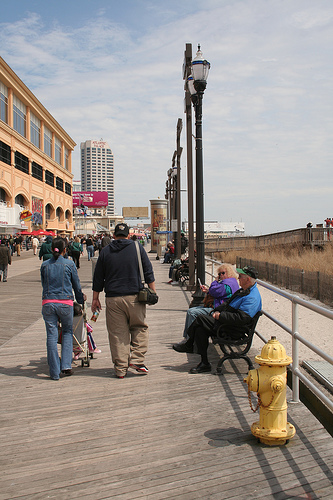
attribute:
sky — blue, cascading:
[1, 0, 332, 236]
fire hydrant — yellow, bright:
[245, 335, 293, 447]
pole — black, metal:
[194, 79, 205, 290]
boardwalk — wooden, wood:
[2, 246, 332, 499]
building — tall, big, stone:
[81, 140, 114, 216]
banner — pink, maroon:
[73, 190, 109, 208]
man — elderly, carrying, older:
[172, 264, 262, 372]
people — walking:
[1, 224, 157, 377]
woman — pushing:
[39, 238, 86, 379]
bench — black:
[212, 310, 263, 375]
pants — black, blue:
[191, 310, 256, 356]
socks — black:
[186, 333, 194, 344]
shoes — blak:
[190, 361, 212, 373]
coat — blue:
[211, 285, 261, 328]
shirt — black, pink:
[96, 241, 155, 299]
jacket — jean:
[42, 256, 79, 304]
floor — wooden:
[2, 250, 332, 499]